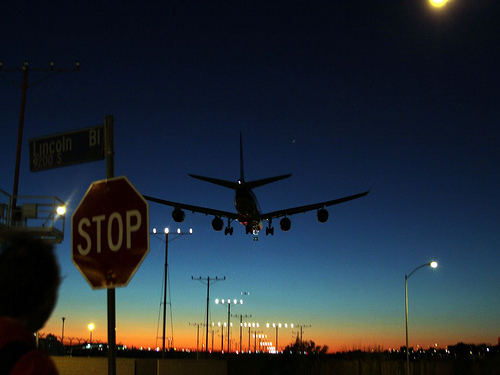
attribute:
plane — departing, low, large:
[126, 125, 385, 236]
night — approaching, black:
[236, 19, 405, 112]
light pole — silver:
[392, 270, 423, 354]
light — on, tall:
[410, 249, 442, 277]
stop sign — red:
[74, 178, 157, 284]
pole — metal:
[86, 277, 127, 374]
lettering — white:
[73, 208, 148, 254]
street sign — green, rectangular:
[36, 130, 115, 174]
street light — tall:
[388, 249, 437, 355]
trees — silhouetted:
[275, 326, 343, 353]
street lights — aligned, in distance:
[165, 223, 297, 359]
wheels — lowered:
[213, 217, 290, 252]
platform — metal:
[4, 193, 77, 235]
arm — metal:
[407, 261, 426, 286]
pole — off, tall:
[0, 60, 80, 196]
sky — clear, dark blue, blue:
[87, 16, 419, 124]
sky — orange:
[320, 307, 491, 352]